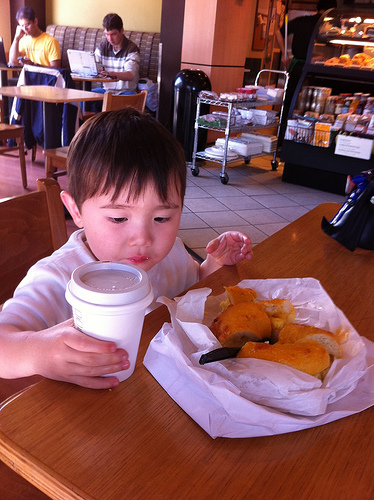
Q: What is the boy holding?
A: A cup.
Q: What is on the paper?
A: Bread.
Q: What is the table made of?
A: Wood.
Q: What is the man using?
A: Computer.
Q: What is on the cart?
A: Containers.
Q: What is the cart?
A: Silver.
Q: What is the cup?
A: White.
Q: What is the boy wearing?
A: Tshirt.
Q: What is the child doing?
A: Eating.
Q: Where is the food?
A: In a cart.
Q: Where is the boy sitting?
A: In a chair.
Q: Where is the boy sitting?
A: At a table.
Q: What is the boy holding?
A: A cup.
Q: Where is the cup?
A: On the table.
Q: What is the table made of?
A: Wood.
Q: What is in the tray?
A: Bread.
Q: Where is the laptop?
A: On the table.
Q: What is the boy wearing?
A: A shirt.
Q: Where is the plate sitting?
A: On the table.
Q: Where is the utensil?
A: In the plate.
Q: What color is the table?
A: Brown.